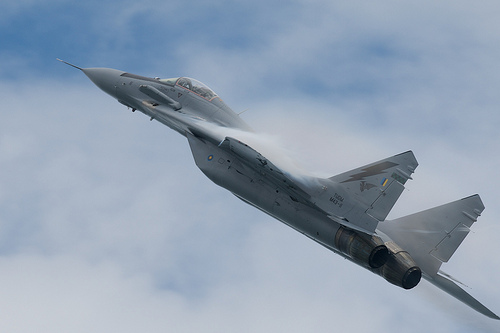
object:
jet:
[53, 57, 500, 320]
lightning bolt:
[339, 161, 400, 184]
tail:
[324, 149, 498, 322]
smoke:
[191, 118, 322, 187]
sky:
[0, 0, 500, 331]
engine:
[335, 227, 423, 290]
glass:
[157, 76, 218, 100]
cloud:
[0, 0, 499, 331]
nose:
[56, 58, 104, 91]